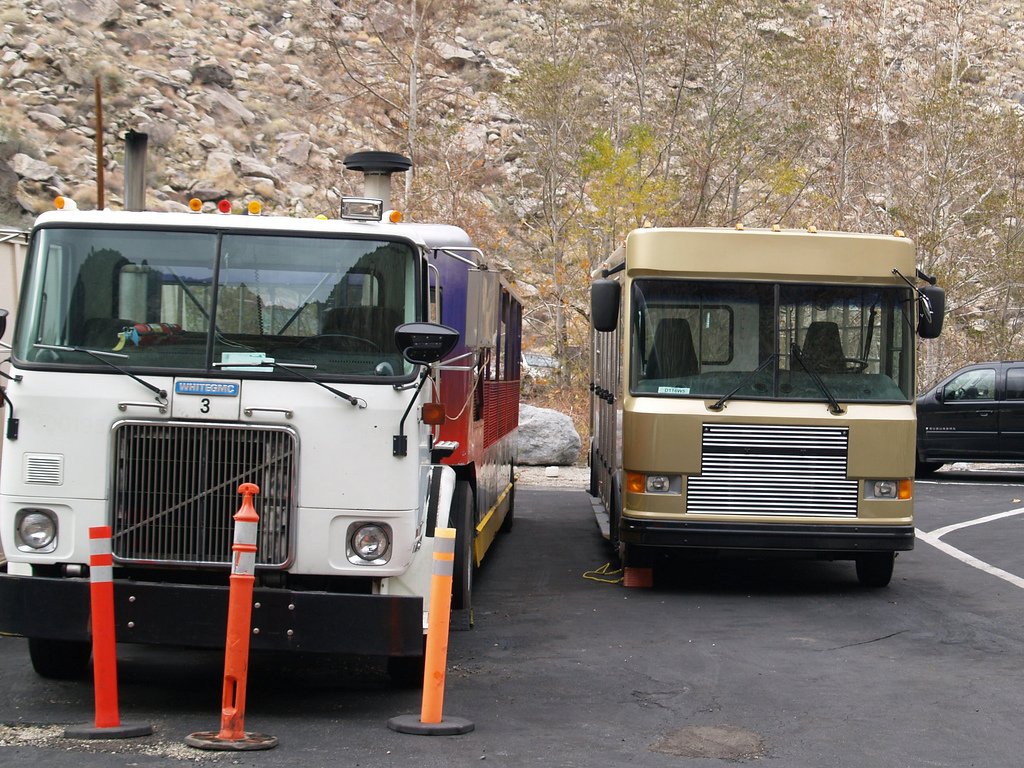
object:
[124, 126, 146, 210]
pipes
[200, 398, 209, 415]
number 3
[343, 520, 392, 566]
headlight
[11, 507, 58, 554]
headlight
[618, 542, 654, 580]
front tire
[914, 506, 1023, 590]
line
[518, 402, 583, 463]
large rock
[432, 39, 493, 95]
rock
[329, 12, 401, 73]
rock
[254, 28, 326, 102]
rock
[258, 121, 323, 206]
rock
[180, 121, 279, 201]
rock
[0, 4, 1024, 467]
hill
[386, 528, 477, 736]
pylon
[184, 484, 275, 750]
pylon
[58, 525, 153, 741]
pylon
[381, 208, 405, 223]
light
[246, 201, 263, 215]
light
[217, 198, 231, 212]
light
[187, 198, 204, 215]
light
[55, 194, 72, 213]
light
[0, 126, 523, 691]
white truck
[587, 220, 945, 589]
bus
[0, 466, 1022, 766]
road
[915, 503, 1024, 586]
white line